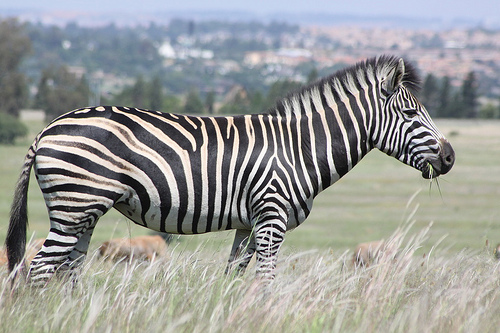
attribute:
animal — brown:
[97, 235, 165, 260]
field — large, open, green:
[1, 226, 497, 331]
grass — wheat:
[0, 105, 496, 332]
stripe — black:
[311, 85, 328, 190]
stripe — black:
[43, 182, 114, 198]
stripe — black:
[43, 240, 75, 247]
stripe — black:
[23, 152, 33, 159]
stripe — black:
[254, 223, 284, 230]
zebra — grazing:
[22, 27, 450, 296]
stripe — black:
[323, 98, 347, 173]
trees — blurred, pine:
[1, 12, 497, 154]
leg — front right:
[247, 193, 288, 293]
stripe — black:
[318, 71, 349, 174]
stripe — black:
[297, 89, 319, 194]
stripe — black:
[344, 58, 369, 153]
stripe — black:
[186, 102, 207, 236]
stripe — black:
[218, 112, 236, 233]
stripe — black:
[361, 64, 401, 149]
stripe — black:
[344, 67, 394, 144]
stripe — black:
[338, 75, 387, 160]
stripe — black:
[316, 74, 378, 169]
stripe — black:
[312, 83, 357, 181]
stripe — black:
[305, 91, 345, 193]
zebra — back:
[0, 54, 454, 288]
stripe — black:
[232, 120, 272, 178]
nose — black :
[409, 123, 470, 219]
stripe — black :
[229, 153, 256, 194]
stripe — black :
[184, 141, 246, 221]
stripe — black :
[162, 110, 239, 194]